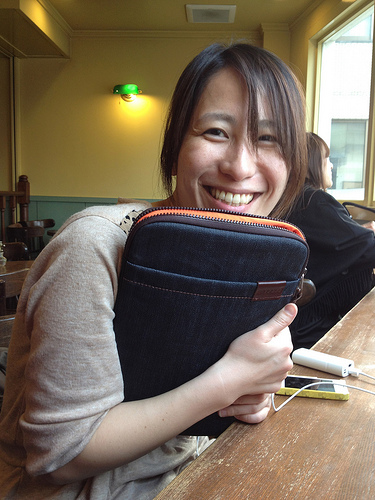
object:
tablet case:
[113, 207, 309, 436]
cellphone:
[276, 373, 349, 400]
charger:
[291, 347, 356, 378]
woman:
[0, 43, 306, 499]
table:
[148, 285, 374, 499]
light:
[113, 84, 139, 102]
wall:
[0, 30, 293, 201]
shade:
[113, 84, 139, 95]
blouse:
[0, 201, 217, 499]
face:
[178, 67, 289, 216]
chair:
[0, 189, 56, 260]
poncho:
[282, 186, 374, 328]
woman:
[281, 131, 374, 356]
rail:
[16, 173, 29, 222]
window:
[313, 0, 373, 202]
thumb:
[263, 301, 299, 337]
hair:
[160, 41, 308, 220]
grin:
[200, 182, 266, 213]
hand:
[231, 302, 298, 393]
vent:
[187, 3, 237, 26]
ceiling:
[0, 1, 319, 57]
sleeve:
[18, 214, 126, 476]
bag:
[342, 202, 374, 226]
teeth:
[231, 194, 242, 204]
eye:
[202, 127, 227, 138]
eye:
[256, 134, 276, 142]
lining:
[134, 209, 305, 239]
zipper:
[129, 205, 311, 297]